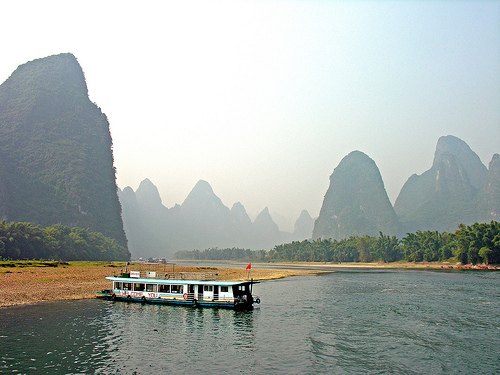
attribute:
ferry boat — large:
[101, 263, 268, 326]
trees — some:
[393, 217, 498, 265]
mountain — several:
[253, 203, 278, 240]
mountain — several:
[229, 199, 253, 241]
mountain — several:
[184, 175, 229, 242]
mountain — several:
[131, 175, 179, 232]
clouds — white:
[3, 0, 313, 167]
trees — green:
[176, 222, 499, 264]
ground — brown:
[0, 254, 350, 301]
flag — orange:
[234, 255, 261, 275]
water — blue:
[325, 296, 478, 361]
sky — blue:
[0, 0, 498, 231]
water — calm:
[0, 237, 495, 374]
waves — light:
[292, 295, 479, 372]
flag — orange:
[230, 248, 265, 299]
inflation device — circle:
[162, 273, 172, 280]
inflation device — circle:
[181, 290, 188, 301]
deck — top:
[103, 273, 255, 288]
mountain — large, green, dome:
[315, 142, 400, 252]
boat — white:
[95, 271, 259, 310]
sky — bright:
[17, 18, 434, 107]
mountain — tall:
[0, 48, 132, 258]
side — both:
[1, 263, 290, 303]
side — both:
[222, 247, 493, 271]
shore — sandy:
[1, 255, 498, 305]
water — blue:
[0, 260, 499, 373]